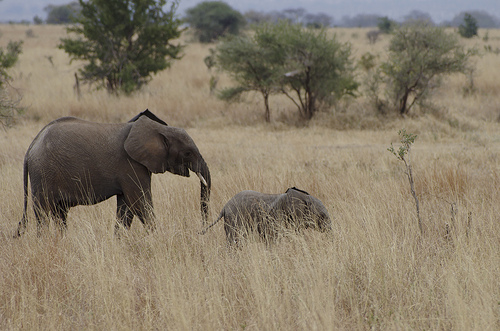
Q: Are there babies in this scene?
A: Yes, there is a baby.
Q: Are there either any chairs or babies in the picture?
A: Yes, there is a baby.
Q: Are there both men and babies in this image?
A: No, there is a baby but no men.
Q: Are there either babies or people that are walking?
A: Yes, the baby is walking.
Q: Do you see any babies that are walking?
A: Yes, there is a baby that is walking.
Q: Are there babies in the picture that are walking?
A: Yes, there is a baby that is walking.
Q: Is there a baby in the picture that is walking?
A: Yes, there is a baby that is walking.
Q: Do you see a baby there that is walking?
A: Yes, there is a baby that is walking.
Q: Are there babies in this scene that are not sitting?
A: Yes, there is a baby that is walking.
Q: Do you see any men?
A: No, there are no men.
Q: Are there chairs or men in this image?
A: No, there are no men or chairs.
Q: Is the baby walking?
A: Yes, the baby is walking.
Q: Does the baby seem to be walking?
A: Yes, the baby is walking.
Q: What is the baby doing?
A: The baby is walking.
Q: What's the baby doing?
A: The baby is walking.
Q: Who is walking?
A: The baby is walking.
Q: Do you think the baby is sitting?
A: No, the baby is walking.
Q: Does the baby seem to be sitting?
A: No, the baby is walking.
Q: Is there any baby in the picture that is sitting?
A: No, there is a baby but he is walking.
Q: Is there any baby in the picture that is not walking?
A: No, there is a baby but he is walking.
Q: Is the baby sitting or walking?
A: The baby is walking.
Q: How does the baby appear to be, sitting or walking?
A: The baby is walking.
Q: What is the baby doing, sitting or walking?
A: The baby is walking.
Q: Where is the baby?
A: The baby is in the grass.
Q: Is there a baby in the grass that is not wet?
A: Yes, there is a baby in the grass.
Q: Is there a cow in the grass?
A: No, there is a baby in the grass.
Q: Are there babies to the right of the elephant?
A: Yes, there is a baby to the right of the elephant.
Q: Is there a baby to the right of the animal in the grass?
A: Yes, there is a baby to the right of the elephant.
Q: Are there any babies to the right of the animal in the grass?
A: Yes, there is a baby to the right of the elephant.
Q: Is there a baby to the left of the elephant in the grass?
A: No, the baby is to the right of the elephant.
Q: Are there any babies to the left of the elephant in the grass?
A: No, the baby is to the right of the elephant.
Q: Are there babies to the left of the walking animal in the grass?
A: No, the baby is to the right of the elephant.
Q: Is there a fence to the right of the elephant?
A: No, there is a baby to the right of the elephant.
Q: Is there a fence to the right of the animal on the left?
A: No, there is a baby to the right of the elephant.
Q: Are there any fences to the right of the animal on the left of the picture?
A: No, there is a baby to the right of the elephant.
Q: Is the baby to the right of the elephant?
A: Yes, the baby is to the right of the elephant.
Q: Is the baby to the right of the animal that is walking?
A: Yes, the baby is to the right of the elephant.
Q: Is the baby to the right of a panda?
A: No, the baby is to the right of the elephant.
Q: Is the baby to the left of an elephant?
A: No, the baby is to the right of an elephant.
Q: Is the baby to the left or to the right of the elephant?
A: The baby is to the right of the elephant.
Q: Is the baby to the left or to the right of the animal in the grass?
A: The baby is to the right of the elephant.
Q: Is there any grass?
A: Yes, there is grass.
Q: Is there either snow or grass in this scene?
A: Yes, there is grass.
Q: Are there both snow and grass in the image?
A: No, there is grass but no snow.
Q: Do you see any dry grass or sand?
A: Yes, there is dry grass.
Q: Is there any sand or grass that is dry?
A: Yes, the grass is dry.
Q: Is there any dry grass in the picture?
A: Yes, there is dry grass.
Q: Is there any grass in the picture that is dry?
A: Yes, there is grass that is dry.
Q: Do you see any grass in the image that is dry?
A: Yes, there is grass that is dry.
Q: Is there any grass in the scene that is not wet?
A: Yes, there is dry grass.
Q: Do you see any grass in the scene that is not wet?
A: Yes, there is dry grass.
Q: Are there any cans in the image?
A: No, there are no cans.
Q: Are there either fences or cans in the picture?
A: No, there are no cans or fences.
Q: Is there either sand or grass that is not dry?
A: No, there is grass but it is dry.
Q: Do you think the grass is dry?
A: Yes, the grass is dry.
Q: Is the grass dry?
A: Yes, the grass is dry.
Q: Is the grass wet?
A: No, the grass is dry.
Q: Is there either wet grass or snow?
A: No, there is grass but it is dry.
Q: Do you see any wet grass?
A: No, there is grass but it is dry.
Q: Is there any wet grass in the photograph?
A: No, there is grass but it is dry.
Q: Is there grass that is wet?
A: No, there is grass but it is dry.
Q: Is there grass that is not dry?
A: No, there is grass but it is dry.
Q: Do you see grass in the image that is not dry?
A: No, there is grass but it is dry.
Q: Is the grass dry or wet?
A: The grass is dry.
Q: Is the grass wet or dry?
A: The grass is dry.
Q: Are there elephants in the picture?
A: Yes, there is an elephant.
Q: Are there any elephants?
A: Yes, there is an elephant.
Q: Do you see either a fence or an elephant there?
A: Yes, there is an elephant.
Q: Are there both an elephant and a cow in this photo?
A: No, there is an elephant but no cows.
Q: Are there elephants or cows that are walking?
A: Yes, the elephant is walking.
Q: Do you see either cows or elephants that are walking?
A: Yes, the elephant is walking.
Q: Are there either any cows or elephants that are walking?
A: Yes, the elephant is walking.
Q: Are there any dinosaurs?
A: No, there are no dinosaurs.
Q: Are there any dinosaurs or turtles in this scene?
A: No, there are no dinosaurs or turtles.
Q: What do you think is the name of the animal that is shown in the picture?
A: The animal is an elephant.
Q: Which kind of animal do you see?
A: The animal is an elephant.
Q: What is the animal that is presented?
A: The animal is an elephant.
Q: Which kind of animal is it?
A: The animal is an elephant.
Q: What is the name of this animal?
A: This is an elephant.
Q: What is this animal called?
A: This is an elephant.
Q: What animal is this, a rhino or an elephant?
A: This is an elephant.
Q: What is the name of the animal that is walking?
A: The animal is an elephant.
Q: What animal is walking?
A: The animal is an elephant.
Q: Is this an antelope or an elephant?
A: This is an elephant.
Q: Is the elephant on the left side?
A: Yes, the elephant is on the left of the image.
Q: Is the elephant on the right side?
A: No, the elephant is on the left of the image.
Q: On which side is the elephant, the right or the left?
A: The elephant is on the left of the image.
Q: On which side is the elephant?
A: The elephant is on the left of the image.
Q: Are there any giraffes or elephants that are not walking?
A: No, there is an elephant but it is walking.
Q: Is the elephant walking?
A: Yes, the elephant is walking.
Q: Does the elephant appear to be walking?
A: Yes, the elephant is walking.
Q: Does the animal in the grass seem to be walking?
A: Yes, the elephant is walking.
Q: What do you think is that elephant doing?
A: The elephant is walking.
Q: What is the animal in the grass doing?
A: The elephant is walking.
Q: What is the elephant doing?
A: The elephant is walking.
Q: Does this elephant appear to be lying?
A: No, the elephant is walking.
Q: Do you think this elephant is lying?
A: No, the elephant is walking.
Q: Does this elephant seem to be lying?
A: No, the elephant is walking.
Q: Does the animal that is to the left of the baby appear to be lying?
A: No, the elephant is walking.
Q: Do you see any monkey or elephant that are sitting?
A: No, there is an elephant but it is walking.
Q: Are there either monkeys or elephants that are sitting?
A: No, there is an elephant but it is walking.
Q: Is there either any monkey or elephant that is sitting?
A: No, there is an elephant but it is walking.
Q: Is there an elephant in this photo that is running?
A: No, there is an elephant but it is walking.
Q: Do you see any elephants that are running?
A: No, there is an elephant but it is walking.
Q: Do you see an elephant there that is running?
A: No, there is an elephant but it is walking.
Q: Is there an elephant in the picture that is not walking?
A: No, there is an elephant but it is walking.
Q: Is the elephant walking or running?
A: The elephant is walking.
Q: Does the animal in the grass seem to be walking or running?
A: The elephant is walking.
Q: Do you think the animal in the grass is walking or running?
A: The elephant is walking.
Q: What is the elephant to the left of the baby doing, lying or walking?
A: The elephant is walking.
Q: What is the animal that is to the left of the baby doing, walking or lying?
A: The elephant is walking.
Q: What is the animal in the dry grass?
A: The animal is an elephant.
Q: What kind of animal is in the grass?
A: The animal is an elephant.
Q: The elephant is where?
A: The elephant is in the grass.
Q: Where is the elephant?
A: The elephant is in the grass.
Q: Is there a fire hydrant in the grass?
A: No, there is an elephant in the grass.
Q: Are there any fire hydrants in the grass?
A: No, there is an elephant in the grass.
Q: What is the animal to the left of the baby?
A: The animal is an elephant.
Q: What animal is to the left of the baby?
A: The animal is an elephant.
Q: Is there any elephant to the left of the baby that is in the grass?
A: Yes, there is an elephant to the left of the baby.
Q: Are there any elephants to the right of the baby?
A: No, the elephant is to the left of the baby.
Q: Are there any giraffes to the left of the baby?
A: No, there is an elephant to the left of the baby.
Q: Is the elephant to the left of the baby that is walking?
A: Yes, the elephant is to the left of the baby.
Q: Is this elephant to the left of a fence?
A: No, the elephant is to the left of the baby.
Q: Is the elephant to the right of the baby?
A: No, the elephant is to the left of the baby.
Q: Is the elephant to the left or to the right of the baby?
A: The elephant is to the left of the baby.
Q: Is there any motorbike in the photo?
A: No, there are no motorcycles.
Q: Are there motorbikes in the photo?
A: No, there are no motorbikes.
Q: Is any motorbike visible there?
A: No, there are no motorcycles.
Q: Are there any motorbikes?
A: No, there are no motorbikes.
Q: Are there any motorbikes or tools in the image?
A: No, there are no motorbikes or tools.